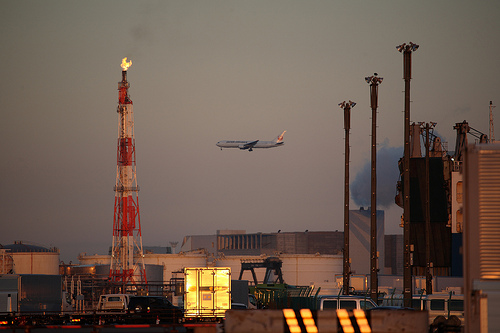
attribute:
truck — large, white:
[180, 264, 232, 323]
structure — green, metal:
[238, 259, 287, 285]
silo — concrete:
[13, 251, 62, 273]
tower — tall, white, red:
[108, 56, 153, 298]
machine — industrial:
[236, 250, 316, 308]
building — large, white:
[190, 222, 395, 304]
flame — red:
[113, 48, 145, 80]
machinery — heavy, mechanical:
[402, 118, 487, 154]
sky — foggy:
[1, 1, 497, 264]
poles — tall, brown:
[326, 33, 421, 303]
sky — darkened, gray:
[2, 3, 499, 227]